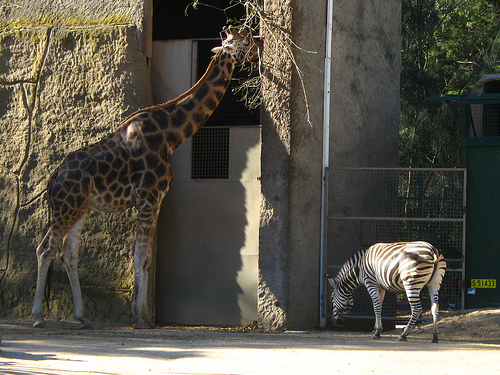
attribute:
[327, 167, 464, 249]
fence — metal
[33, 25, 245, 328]
giraffe — eating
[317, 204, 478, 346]
zebra — black, white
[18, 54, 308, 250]
giraffe — long neck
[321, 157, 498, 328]
fence —  chain link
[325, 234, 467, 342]
zebra — small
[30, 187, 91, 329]
giraffe`s legs — back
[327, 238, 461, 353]
zebra — bending down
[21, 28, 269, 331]
giraffe — spotted, tall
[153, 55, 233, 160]
neck — long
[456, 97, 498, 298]
partition — green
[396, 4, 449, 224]
tree — large